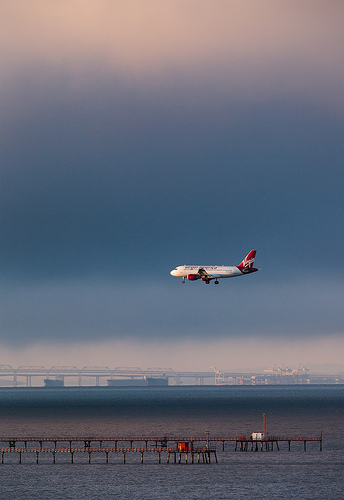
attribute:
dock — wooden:
[4, 447, 222, 466]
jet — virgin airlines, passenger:
[147, 241, 264, 298]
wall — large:
[0, 383, 344, 399]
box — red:
[174, 438, 190, 450]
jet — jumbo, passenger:
[168, 248, 261, 284]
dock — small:
[0, 435, 322, 451]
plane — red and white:
[166, 245, 258, 285]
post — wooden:
[207, 447, 222, 463]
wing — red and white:
[237, 249, 256, 267]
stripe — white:
[241, 256, 255, 264]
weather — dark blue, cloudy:
[4, 10, 337, 499]